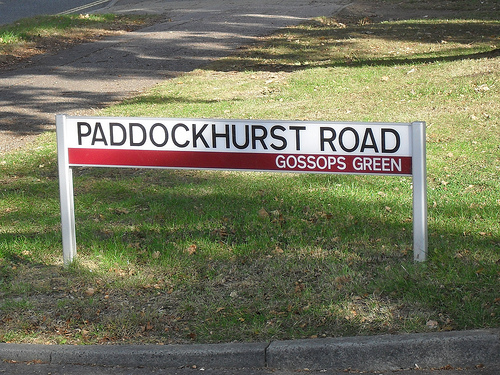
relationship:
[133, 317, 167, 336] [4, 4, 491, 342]
leaves on grass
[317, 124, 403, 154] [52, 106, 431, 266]
road written on sign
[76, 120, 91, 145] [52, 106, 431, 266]
letter on sign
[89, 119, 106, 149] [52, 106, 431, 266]
letter on sign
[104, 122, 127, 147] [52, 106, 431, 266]
letter on sign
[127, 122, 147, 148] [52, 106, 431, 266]
letter on sign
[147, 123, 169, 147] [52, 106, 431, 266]
letter on sign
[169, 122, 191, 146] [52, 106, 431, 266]
letter on sign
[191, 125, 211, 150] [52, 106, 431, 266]
letter on sign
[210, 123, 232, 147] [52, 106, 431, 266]
letter on sign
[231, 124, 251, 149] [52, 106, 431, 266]
letter on sign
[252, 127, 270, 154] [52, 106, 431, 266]
letter on sign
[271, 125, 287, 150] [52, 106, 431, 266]
letter on sign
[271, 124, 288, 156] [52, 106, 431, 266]
letter on sign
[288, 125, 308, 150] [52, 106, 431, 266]
black letter on sign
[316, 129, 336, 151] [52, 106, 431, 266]
letter on sign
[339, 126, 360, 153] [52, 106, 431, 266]
letter on sign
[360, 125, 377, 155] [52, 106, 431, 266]
letter on sign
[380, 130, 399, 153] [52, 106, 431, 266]
letter on sign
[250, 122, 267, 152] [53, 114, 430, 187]
black letter on sign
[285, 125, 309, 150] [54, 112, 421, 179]
black letter on sign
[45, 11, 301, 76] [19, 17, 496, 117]
shadows on ground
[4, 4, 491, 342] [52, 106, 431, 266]
grass under sign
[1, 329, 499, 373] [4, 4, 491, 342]
curb along grass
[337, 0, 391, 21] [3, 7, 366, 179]
dirt beside road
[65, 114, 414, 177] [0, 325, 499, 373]
sign next to street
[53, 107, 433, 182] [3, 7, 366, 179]
sign near road